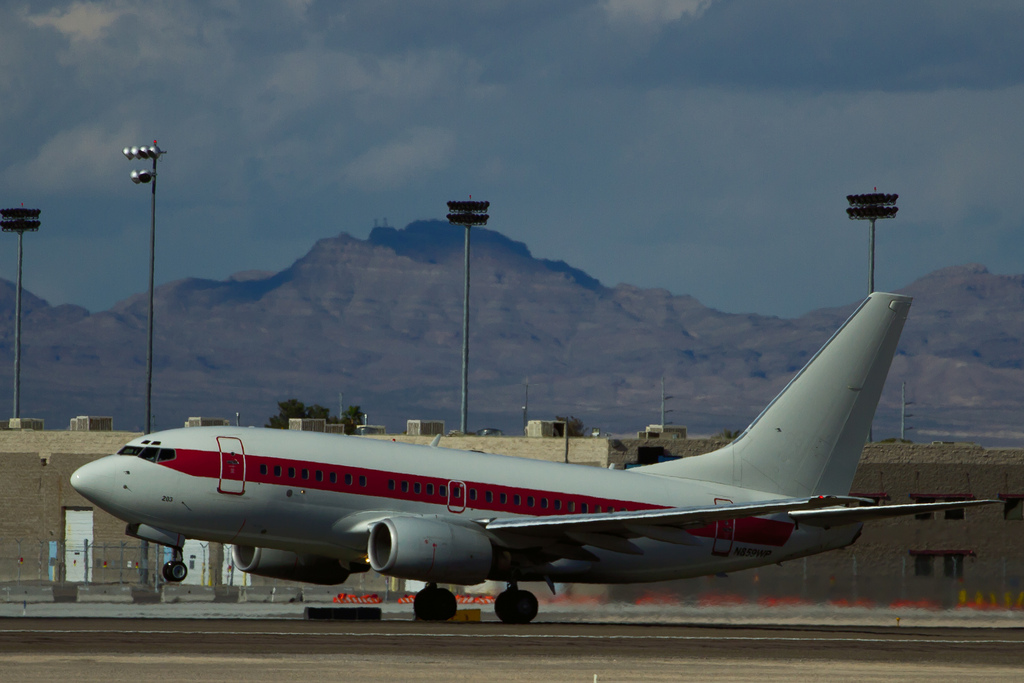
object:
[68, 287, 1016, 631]
plane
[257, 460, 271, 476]
window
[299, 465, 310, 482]
window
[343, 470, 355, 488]
window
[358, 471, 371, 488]
window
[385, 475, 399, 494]
window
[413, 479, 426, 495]
window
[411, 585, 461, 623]
tires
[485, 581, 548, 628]
tires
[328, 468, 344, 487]
windows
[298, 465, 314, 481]
windows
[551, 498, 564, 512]
windows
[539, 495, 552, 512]
windows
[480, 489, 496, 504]
windows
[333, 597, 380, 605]
stripe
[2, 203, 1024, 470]
mountain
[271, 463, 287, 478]
window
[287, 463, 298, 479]
window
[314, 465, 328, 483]
window